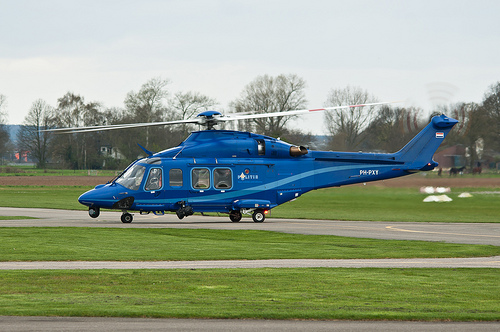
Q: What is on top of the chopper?
A: Propeller.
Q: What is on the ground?
A: Grass and asphalt.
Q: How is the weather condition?
A: Overcast.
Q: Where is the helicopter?
A: On the landing.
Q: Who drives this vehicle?
A: A pilot.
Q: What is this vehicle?
A: A helicopter.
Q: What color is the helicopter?
A: Blue.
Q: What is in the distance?
A: Trees.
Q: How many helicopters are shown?
A: One.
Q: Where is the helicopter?
A: On the landing strip.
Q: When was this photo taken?
A: During the daytime.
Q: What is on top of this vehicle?
A: A rotor.